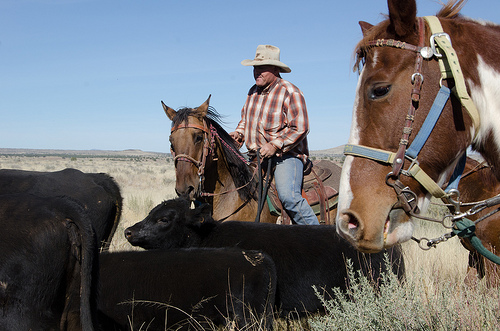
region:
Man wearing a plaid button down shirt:
[232, 45, 314, 166]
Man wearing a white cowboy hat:
[237, 37, 290, 91]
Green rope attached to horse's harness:
[442, 210, 497, 265]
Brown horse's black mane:
[155, 99, 260, 224]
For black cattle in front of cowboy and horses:
[2, 162, 402, 324]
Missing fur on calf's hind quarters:
[232, 244, 269, 273]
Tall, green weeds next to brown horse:
[305, 251, 498, 329]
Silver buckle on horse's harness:
[415, 12, 467, 78]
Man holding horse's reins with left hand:
[220, 138, 286, 221]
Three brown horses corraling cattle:
[145, 1, 498, 298]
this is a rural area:
[83, 35, 448, 285]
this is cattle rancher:
[233, 60, 348, 200]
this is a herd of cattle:
[27, 166, 237, 321]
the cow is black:
[111, 190, 276, 262]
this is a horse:
[365, 35, 495, 260]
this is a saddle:
[250, 170, 330, 207]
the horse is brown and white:
[300, 3, 477, 196]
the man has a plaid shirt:
[205, 97, 320, 152]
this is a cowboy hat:
[228, 23, 341, 92]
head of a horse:
[322, 16, 470, 248]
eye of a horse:
[354, 72, 421, 113]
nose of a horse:
[320, 196, 370, 250]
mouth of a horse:
[362, 197, 431, 258]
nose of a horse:
[165, 170, 197, 198]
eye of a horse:
[186, 124, 210, 148]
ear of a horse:
[155, 96, 190, 123]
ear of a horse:
[189, 82, 229, 118]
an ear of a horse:
[193, 82, 230, 115]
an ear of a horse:
[157, 90, 182, 130]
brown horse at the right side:
[346, 8, 493, 263]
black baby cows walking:
[129, 198, 280, 329]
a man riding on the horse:
[165, 44, 329, 219]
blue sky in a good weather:
[72, 20, 169, 66]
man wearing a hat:
[243, 35, 298, 77]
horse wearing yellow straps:
[446, 19, 481, 106]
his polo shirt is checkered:
[236, 79, 311, 162]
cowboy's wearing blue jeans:
[269, 161, 316, 232]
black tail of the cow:
[69, 218, 103, 325]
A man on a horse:
[14, 8, 493, 321]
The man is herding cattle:
[0, 33, 410, 325]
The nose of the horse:
[331, 201, 365, 247]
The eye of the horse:
[363, 75, 395, 107]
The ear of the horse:
[191, 90, 215, 121]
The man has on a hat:
[239, 44, 293, 77]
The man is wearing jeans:
[263, 152, 323, 228]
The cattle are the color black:
[0, 161, 400, 326]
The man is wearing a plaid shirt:
[235, 80, 315, 167]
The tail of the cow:
[57, 196, 114, 329]